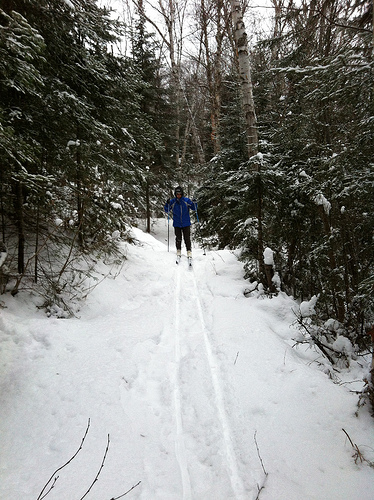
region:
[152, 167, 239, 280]
A person is skiing.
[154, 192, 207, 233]
The skier's jacket is blue.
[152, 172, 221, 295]
The skier is cross country skiing.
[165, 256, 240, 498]
The skier skies in tracks.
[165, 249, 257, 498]
The tracks are in the snow.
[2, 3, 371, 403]
The trail is surrounded by trees.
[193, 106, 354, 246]
Snow is on the trees.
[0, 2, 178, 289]
The trees are pine trees.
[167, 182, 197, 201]
The skier wears a hat.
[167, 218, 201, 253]
The skier wears dark pants.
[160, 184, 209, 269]
A woman is skiing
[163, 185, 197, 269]
The skier is wearing a blue jacket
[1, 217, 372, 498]
The ground is covered in snow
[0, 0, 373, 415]
Tall trees are around the ski trail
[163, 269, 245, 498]
Ski tracks in the snow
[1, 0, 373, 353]
a bunch of pine trees surround skier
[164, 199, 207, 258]
Ski poles in each of the skier's hands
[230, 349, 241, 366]
A stick in the snow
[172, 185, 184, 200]
Jacket hood is on skier's head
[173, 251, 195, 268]
Skis on the skier's feet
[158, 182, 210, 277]
A PERSON CROSS-COUNTRY SKIING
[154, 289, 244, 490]
TWO SKI TRACKS IN THE SNOW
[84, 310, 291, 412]
THE SNOW IS WHITE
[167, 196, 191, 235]
THE COAT IS BLUE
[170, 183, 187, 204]
THE PERSON IS WEARING A HAT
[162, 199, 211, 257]
THE PERSON IS HOLDING POLES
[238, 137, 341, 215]
THERE IS SNOW ON THE TREES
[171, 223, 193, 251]
THE PERSON IS WEARING BLACK PANTS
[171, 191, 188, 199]
THE PERSON IS WEARING SUNGLASSES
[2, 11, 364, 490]
a person skiing through a forrest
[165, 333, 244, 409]
tracks in the snow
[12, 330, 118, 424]
the snow is white and loose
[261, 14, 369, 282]
the trees are green and covered in snow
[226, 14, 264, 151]
a long tree trunk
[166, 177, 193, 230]
a blue hooded jacket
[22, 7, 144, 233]
small snow covered trees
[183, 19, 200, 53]
the sky is cloudy and gray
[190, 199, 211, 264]
the man holds ski brakes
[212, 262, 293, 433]
the slope is steep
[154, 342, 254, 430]
Ski track marks in the snow.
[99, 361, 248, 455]
Snow covering the ground.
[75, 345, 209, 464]
Snow on the ground is white.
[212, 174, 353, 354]
Tree branches have snow on them.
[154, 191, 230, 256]
Person wearing blue jacket.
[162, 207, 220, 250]
Person holding two ski poles.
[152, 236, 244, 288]
Person has 2 skis on feet.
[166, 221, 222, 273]
Person wearing black pants.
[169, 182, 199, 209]
Person has hat on head.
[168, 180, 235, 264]
Person is cross country skiing.